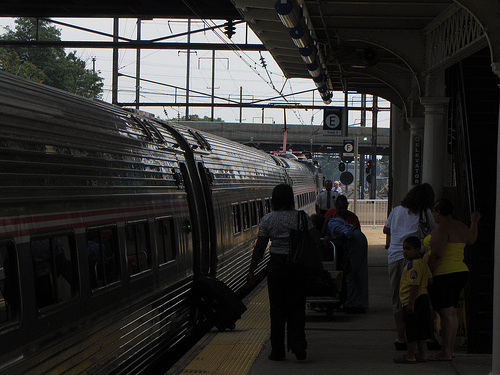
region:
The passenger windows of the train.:
[10, 178, 324, 303]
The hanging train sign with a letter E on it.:
[317, 106, 340, 133]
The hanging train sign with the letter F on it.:
[341, 138, 353, 159]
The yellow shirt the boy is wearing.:
[393, 259, 431, 305]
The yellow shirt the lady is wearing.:
[422, 231, 466, 275]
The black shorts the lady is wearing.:
[437, 269, 467, 310]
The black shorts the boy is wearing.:
[402, 298, 436, 343]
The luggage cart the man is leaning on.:
[310, 231, 349, 316]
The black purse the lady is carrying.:
[285, 208, 324, 288]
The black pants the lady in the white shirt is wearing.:
[265, 249, 310, 357]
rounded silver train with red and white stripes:
[1, 71, 324, 372]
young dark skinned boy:
[397, 235, 434, 364]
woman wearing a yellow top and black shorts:
[420, 195, 468, 364]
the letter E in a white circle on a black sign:
[321, 106, 342, 133]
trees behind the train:
[1, 53, 106, 99]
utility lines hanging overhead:
[71, 53, 382, 137]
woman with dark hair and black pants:
[246, 182, 325, 361]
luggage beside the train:
[195, 270, 249, 332]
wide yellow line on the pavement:
[177, 279, 271, 374]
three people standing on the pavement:
[383, 180, 480, 365]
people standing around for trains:
[244, 171, 481, 360]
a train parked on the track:
[3, 75, 325, 374]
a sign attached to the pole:
[320, 99, 346, 145]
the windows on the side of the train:
[1, 213, 180, 333]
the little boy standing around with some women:
[393, 234, 428, 369]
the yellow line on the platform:
[180, 287, 262, 374]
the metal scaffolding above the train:
[137, 58, 317, 113]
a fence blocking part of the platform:
[339, 196, 390, 227]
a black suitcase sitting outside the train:
[183, 264, 245, 331]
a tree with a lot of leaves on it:
[6, 20, 101, 98]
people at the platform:
[256, 157, 370, 341]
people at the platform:
[364, 155, 451, 322]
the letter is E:
[310, 98, 352, 137]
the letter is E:
[294, 87, 371, 154]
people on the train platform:
[255, 176, 473, 361]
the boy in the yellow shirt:
[389, 235, 436, 302]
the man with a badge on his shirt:
[311, 178, 345, 214]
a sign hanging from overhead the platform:
[315, 107, 348, 138]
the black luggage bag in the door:
[197, 269, 247, 337]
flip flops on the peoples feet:
[391, 347, 468, 371]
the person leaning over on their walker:
[311, 209, 377, 317]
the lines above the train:
[173, 21, 253, 132]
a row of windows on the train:
[2, 209, 178, 331]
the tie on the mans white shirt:
[323, 189, 333, 211]